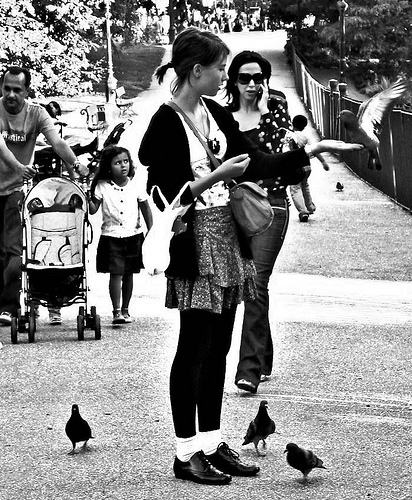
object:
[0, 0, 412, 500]
picture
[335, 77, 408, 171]
pigeon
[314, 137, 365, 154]
hand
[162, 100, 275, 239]
purse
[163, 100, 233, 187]
strap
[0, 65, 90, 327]
man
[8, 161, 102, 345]
stroller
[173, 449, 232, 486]
shoes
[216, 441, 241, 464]
shoe laces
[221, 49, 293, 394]
woman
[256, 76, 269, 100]
cell phone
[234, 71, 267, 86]
sunglasses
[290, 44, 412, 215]
fence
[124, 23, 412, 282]
walkway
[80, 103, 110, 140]
bench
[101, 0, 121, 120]
post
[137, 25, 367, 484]
woman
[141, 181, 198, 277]
bag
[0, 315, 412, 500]
street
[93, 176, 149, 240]
shirt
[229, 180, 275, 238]
bag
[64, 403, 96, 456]
birds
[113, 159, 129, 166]
away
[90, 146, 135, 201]
dark hair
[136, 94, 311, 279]
shirt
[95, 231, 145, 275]
skirt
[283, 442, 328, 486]
bird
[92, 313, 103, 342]
wheels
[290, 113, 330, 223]
people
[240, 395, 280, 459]
pigeon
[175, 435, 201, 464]
socks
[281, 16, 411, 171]
air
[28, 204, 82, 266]
baby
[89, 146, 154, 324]
girl